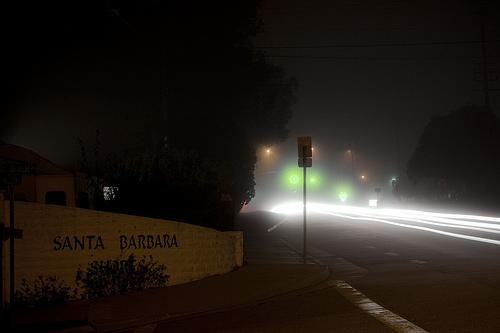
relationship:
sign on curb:
[5, 186, 251, 314] [9, 203, 424, 332]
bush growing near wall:
[62, 239, 183, 309] [0, 196, 245, 306]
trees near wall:
[106, 96, 266, 207] [0, 196, 245, 306]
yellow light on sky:
[261, 142, 280, 163] [236, 0, 486, 196]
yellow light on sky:
[306, 140, 321, 155] [236, 0, 486, 196]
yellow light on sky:
[356, 170, 368, 185] [236, 0, 486, 196]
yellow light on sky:
[339, 143, 356, 163] [236, 0, 486, 196]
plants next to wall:
[74, 256, 176, 327] [5, 196, 262, 321]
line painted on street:
[336, 281, 406, 331] [317, 210, 497, 310]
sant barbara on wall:
[34, 222, 211, 258] [8, 194, 250, 298]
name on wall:
[54, 228, 197, 261] [8, 194, 250, 298]